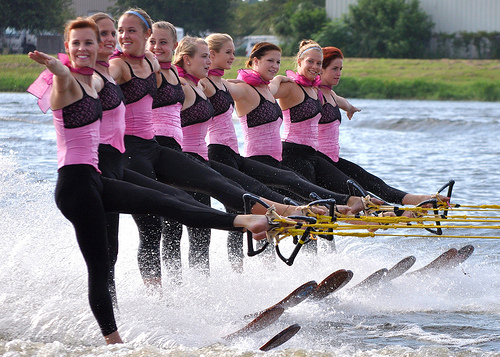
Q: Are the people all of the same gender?
A: Yes, all the people are female.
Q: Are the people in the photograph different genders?
A: No, all the people are female.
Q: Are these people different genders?
A: No, all the people are female.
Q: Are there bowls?
A: No, there are no bowls.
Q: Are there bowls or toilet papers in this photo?
A: No, there are no bowls or toilet papers.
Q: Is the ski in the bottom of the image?
A: Yes, the ski is in the bottom of the image.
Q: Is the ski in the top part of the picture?
A: No, the ski is in the bottom of the image.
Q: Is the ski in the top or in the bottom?
A: The ski is in the bottom of the image.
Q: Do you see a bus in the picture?
A: No, there are no buses.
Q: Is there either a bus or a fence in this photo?
A: No, there are no buses or fences.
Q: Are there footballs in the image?
A: No, there are no footballs.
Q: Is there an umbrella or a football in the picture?
A: No, there are no footballs or umbrellas.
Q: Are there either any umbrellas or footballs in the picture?
A: No, there are no footballs or umbrellas.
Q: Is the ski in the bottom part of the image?
A: Yes, the ski is in the bottom of the image.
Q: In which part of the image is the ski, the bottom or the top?
A: The ski is in the bottom of the image.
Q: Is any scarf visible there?
A: Yes, there is a scarf.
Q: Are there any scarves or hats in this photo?
A: Yes, there is a scarf.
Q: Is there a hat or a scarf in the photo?
A: Yes, there is a scarf.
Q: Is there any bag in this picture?
A: No, there are no bags.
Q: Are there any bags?
A: No, there are no bags.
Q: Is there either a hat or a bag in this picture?
A: No, there are no bags or hats.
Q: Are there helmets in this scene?
A: No, there are no helmets.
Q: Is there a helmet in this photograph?
A: No, there are no helmets.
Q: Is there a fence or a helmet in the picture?
A: No, there are no helmets or fences.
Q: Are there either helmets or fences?
A: No, there are no helmets or fences.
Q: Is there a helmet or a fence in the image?
A: No, there are no helmets or fences.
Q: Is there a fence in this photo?
A: No, there are no fences.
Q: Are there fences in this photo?
A: No, there are no fences.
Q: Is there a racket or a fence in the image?
A: No, there are no fences or rackets.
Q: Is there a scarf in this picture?
A: Yes, there is a scarf.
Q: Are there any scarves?
A: Yes, there is a scarf.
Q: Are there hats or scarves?
A: Yes, there is a scarf.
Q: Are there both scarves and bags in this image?
A: No, there is a scarf but no bags.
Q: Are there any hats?
A: No, there are no hats.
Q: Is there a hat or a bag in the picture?
A: No, there are no hats or bags.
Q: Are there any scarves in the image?
A: Yes, there is a scarf.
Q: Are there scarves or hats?
A: Yes, there is a scarf.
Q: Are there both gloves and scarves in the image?
A: No, there is a scarf but no gloves.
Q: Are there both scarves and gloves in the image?
A: No, there is a scarf but no gloves.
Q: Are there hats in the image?
A: No, there are no hats.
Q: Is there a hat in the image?
A: No, there are no hats.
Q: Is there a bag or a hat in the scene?
A: No, there are no hats or bags.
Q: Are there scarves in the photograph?
A: Yes, there is a scarf.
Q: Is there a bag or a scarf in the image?
A: Yes, there is a scarf.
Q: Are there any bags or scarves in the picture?
A: Yes, there is a scarf.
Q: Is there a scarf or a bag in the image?
A: Yes, there is a scarf.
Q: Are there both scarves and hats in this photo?
A: No, there is a scarf but no hats.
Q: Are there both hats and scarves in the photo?
A: No, there is a scarf but no hats.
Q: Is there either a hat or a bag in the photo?
A: No, there are no hats or bags.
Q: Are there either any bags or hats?
A: No, there are no hats or bags.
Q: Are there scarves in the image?
A: Yes, there is a scarf.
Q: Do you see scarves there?
A: Yes, there is a scarf.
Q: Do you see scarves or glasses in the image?
A: Yes, there is a scarf.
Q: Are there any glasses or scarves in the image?
A: Yes, there is a scarf.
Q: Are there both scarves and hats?
A: No, there is a scarf but no hats.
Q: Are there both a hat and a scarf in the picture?
A: No, there is a scarf but no hats.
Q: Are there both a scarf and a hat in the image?
A: No, there is a scarf but no hats.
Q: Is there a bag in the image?
A: No, there are no bags.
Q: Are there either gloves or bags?
A: No, there are no bags or gloves.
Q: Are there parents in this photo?
A: No, there are no parents.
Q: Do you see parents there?
A: No, there are no parents.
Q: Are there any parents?
A: No, there are no parents.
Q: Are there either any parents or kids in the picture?
A: No, there are no parents or kids.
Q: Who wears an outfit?
A: The lady wears an outfit.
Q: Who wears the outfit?
A: The lady wears an outfit.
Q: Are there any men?
A: No, there are no men.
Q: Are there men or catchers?
A: No, there are no men or catchers.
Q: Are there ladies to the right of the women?
A: Yes, there is a lady to the right of the women.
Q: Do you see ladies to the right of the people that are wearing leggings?
A: Yes, there is a lady to the right of the women.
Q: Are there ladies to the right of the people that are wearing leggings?
A: Yes, there is a lady to the right of the women.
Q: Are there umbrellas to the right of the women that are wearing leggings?
A: No, there is a lady to the right of the women.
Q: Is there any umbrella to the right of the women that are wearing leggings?
A: No, there is a lady to the right of the women.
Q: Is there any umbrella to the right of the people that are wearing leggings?
A: No, there is a lady to the right of the women.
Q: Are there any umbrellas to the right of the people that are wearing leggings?
A: No, there is a lady to the right of the women.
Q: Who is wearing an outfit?
A: The lady is wearing an outfit.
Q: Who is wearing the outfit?
A: The lady is wearing an outfit.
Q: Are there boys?
A: No, there are no boys.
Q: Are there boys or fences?
A: No, there are no boys or fences.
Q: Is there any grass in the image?
A: Yes, there is grass.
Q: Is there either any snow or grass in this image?
A: Yes, there is grass.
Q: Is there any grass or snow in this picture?
A: Yes, there is grass.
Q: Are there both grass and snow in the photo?
A: No, there is grass but no snow.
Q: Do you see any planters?
A: No, there are no planters.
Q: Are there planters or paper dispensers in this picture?
A: No, there are no planters or paper dispensers.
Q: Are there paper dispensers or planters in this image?
A: No, there are no planters or paper dispensers.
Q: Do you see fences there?
A: No, there are no fences.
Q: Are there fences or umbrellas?
A: No, there are no fences or umbrellas.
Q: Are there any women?
A: Yes, there are women.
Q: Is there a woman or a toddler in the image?
A: Yes, there are women.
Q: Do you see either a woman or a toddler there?
A: Yes, there are women.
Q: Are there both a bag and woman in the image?
A: No, there are women but no bags.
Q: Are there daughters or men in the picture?
A: No, there are no men or daughters.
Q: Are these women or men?
A: These are women.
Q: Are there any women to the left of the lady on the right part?
A: Yes, there are women to the left of the lady.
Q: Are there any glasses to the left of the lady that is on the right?
A: No, there are women to the left of the lady.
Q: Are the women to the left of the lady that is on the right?
A: Yes, the women are to the left of the lady.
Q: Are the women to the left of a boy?
A: No, the women are to the left of the lady.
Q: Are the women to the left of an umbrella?
A: No, the women are to the left of a ski.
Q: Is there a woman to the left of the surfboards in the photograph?
A: Yes, there are women to the left of the surfboards.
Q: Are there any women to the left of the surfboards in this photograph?
A: Yes, there are women to the left of the surfboards.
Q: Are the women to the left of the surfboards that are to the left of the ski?
A: Yes, the women are to the left of the surfboards.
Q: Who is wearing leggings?
A: The women are wearing leggings.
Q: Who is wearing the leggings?
A: The women are wearing leggings.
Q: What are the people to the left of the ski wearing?
A: The women are wearing leggings.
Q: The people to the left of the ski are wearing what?
A: The women are wearing leggings.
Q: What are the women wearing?
A: The women are wearing leggings.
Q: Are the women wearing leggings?
A: Yes, the women are wearing leggings.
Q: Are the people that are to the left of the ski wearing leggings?
A: Yes, the women are wearing leggings.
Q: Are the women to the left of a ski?
A: Yes, the women are to the left of a ski.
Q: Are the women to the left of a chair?
A: No, the women are to the left of a ski.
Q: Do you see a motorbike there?
A: No, there are no motorcycles.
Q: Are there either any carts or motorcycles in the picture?
A: No, there are no motorcycles or carts.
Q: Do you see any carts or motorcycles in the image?
A: No, there are no motorcycles or carts.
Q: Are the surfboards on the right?
A: Yes, the surfboards are on the right of the image.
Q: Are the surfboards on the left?
A: No, the surfboards are on the right of the image.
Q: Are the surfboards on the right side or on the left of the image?
A: The surfboards are on the right of the image.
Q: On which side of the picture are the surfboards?
A: The surfboards are on the right of the image.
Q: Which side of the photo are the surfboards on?
A: The surfboards are on the right of the image.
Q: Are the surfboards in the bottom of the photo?
A: Yes, the surfboards are in the bottom of the image.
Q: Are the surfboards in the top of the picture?
A: No, the surfboards are in the bottom of the image.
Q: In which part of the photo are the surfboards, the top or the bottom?
A: The surfboards are in the bottom of the image.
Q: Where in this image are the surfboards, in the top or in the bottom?
A: The surfboards are in the bottom of the image.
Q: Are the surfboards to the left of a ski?
A: Yes, the surfboards are to the left of a ski.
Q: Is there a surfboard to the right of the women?
A: Yes, there are surfboards to the right of the women.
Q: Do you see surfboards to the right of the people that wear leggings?
A: Yes, there are surfboards to the right of the women.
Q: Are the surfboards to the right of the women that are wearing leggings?
A: Yes, the surfboards are to the right of the women.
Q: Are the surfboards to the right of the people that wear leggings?
A: Yes, the surfboards are to the right of the women.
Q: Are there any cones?
A: No, there are no cones.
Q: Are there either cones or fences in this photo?
A: No, there are no cones or fences.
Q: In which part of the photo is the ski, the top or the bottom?
A: The ski is in the bottom of the image.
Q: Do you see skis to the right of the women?
A: Yes, there is a ski to the right of the women.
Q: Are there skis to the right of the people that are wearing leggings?
A: Yes, there is a ski to the right of the women.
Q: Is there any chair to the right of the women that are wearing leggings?
A: No, there is a ski to the right of the women.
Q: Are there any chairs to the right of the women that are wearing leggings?
A: No, there is a ski to the right of the women.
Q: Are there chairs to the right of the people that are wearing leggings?
A: No, there is a ski to the right of the women.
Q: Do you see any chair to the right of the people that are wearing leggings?
A: No, there is a ski to the right of the women.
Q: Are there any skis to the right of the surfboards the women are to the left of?
A: Yes, there is a ski to the right of the surfboards.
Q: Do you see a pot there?
A: No, there are no pots.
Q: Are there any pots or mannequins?
A: No, there are no pots or mannequins.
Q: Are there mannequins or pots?
A: No, there are no pots or mannequins.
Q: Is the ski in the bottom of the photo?
A: Yes, the ski is in the bottom of the image.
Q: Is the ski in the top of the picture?
A: No, the ski is in the bottom of the image.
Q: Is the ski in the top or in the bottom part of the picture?
A: The ski is in the bottom of the image.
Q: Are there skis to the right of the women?
A: Yes, there is a ski to the right of the women.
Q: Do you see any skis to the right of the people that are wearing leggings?
A: Yes, there is a ski to the right of the women.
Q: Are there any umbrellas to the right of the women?
A: No, there is a ski to the right of the women.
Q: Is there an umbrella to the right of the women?
A: No, there is a ski to the right of the women.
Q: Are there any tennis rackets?
A: No, there are no tennis rackets.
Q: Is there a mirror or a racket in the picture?
A: No, there are no rackets or mirrors.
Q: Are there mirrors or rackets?
A: No, there are no rackets or mirrors.